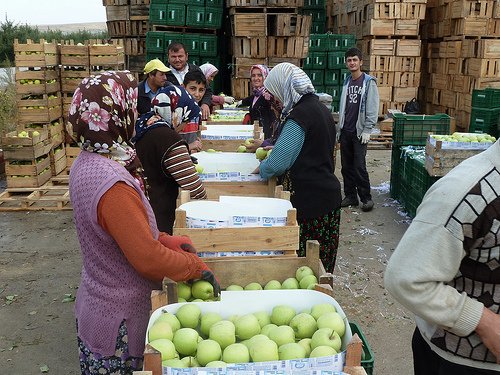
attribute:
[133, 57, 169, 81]
cap — yellow, ball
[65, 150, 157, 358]
sweater vest — lavender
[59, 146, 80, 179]
crate — brown, wood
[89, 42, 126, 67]
crate — brown, wood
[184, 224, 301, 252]
wooden crates — stacked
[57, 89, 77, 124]
crate — wood, brown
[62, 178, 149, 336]
shirt — plaid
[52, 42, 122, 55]
wood crate — brown